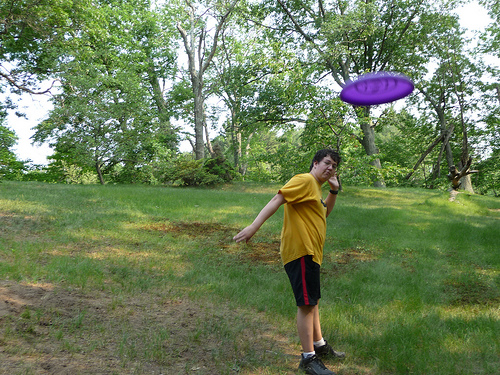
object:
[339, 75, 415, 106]
frisbee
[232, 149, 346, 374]
boy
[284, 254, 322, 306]
shorts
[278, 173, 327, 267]
shirt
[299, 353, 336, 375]
shoe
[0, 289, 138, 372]
ground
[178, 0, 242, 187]
trees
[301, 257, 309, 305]
stripe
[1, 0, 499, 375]
scene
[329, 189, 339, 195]
watch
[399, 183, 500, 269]
grass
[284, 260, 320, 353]
legs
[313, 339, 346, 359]
shoe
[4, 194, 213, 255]
grass spot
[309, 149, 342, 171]
hair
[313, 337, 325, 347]
sock